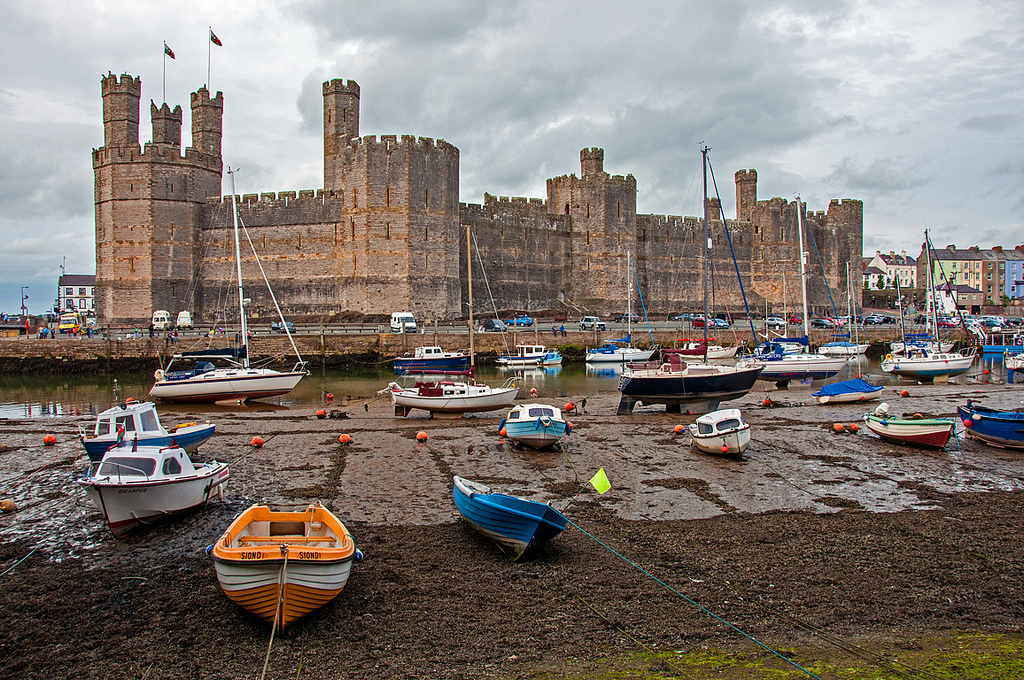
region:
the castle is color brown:
[71, 19, 887, 343]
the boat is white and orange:
[198, 488, 364, 632]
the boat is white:
[77, 437, 243, 533]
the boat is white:
[679, 399, 766, 463]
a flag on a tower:
[182, 18, 240, 165]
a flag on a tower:
[150, 28, 192, 156]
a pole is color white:
[220, 157, 269, 373]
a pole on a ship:
[789, 187, 828, 358]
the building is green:
[928, 244, 968, 296]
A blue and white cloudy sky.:
[0, 1, 1022, 308]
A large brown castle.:
[87, 73, 865, 329]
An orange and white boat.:
[210, 501, 354, 634]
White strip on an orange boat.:
[213, 557, 354, 592]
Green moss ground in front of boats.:
[602, 643, 1021, 678]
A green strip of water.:
[3, 365, 1022, 413]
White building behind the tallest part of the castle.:
[57, 273, 97, 324]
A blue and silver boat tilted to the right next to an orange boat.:
[449, 472, 568, 564]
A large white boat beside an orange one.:
[74, 441, 231, 540]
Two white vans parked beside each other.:
[149, 308, 194, 329]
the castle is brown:
[69, 76, 879, 330]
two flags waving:
[157, 28, 221, 133]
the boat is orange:
[209, 503, 347, 634]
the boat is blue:
[449, 495, 573, 552]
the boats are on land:
[65, 325, 1005, 655]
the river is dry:
[0, 331, 1023, 671]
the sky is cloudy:
[2, 6, 1021, 254]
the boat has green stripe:
[865, 411, 961, 447]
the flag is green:
[585, 462, 617, 494]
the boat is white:
[89, 456, 235, 515]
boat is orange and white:
[209, 495, 361, 629]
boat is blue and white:
[452, 471, 567, 557]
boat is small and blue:
[503, 404, 568, 443]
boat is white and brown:
[88, 442, 226, 523]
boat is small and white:
[686, 405, 751, 457]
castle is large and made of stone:
[94, 67, 866, 333]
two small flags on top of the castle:
[158, 18, 223, 113]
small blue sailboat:
[628, 145, 764, 406]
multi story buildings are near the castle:
[862, 243, 1022, 307]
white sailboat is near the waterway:
[147, 167, 309, 405]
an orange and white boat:
[209, 491, 371, 644]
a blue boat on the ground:
[452, 456, 567, 578]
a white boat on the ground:
[83, 447, 240, 537]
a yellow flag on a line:
[576, 441, 622, 496]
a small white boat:
[850, 399, 962, 461]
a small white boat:
[687, 408, 751, 473]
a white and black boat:
[614, 317, 780, 434]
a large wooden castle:
[88, 44, 873, 348]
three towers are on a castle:
[88, 38, 231, 176]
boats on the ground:
[41, 271, 1016, 677]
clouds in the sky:
[252, 4, 958, 384]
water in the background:
[69, 341, 649, 446]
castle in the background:
[47, 28, 997, 677]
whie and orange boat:
[231, 437, 368, 633]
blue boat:
[430, 449, 547, 554]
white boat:
[672, 399, 748, 466]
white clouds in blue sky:
[301, 4, 382, 47]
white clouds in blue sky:
[485, 7, 587, 88]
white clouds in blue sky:
[669, 7, 771, 91]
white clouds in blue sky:
[418, 48, 479, 94]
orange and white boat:
[213, 493, 353, 629]